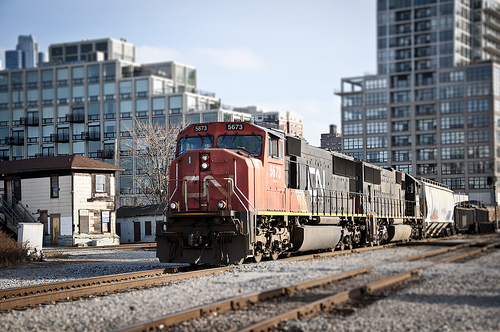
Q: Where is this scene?
A: Cityscape.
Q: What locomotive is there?
A: Train.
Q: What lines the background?
A: Skyscrapers.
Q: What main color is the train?
A: Red.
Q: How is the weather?
A: Fair.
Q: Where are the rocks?
A: Between tracks.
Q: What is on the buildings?
A: Windows.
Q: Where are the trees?
A: Left side.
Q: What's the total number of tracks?
A: 2.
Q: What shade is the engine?
A: Red.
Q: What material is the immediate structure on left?
A: Wood.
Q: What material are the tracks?
A: Metal.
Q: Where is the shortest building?
A: Right side of train.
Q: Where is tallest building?
A: Behind train.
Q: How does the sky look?
A: Clear with some clouds.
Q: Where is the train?
A: On the train track.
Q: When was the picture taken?
A: The picture was taken during the day.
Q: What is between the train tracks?
A: There is gravel.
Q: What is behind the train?
A: There are tall buildings.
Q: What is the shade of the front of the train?
A: It is red.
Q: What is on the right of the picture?
A: A tall building.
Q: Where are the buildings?
A: Behind the train.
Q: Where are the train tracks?
A: Under the train.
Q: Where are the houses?
A: On the left of the picture.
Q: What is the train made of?
A: Metal.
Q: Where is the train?
A: On the tracks.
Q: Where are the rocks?
A: On the ground.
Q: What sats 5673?
A: Numbers on the train.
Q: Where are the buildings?
A: Behind the train.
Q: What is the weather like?
A: Sunny.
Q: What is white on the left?
A: The house.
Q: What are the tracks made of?
A: Steel.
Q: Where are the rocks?
A: The ground.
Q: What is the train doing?
A: Driving.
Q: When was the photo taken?
A: Daytime.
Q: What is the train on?
A: Tracks.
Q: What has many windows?
A: Buildings.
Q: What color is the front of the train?
A: Red.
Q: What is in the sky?
A: Clouds.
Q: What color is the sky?
A: Blue.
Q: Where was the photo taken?
A: At the rail station.